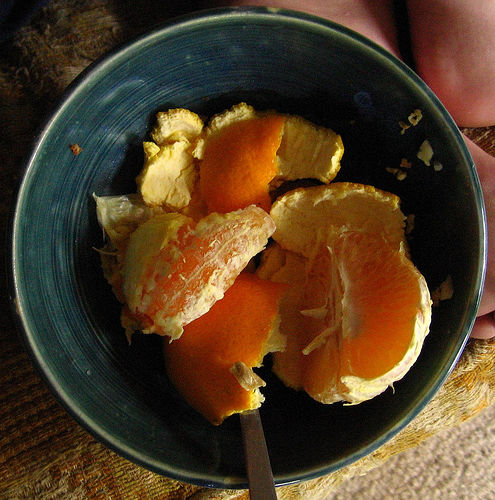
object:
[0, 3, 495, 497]
bowl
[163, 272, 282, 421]
peel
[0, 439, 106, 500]
counter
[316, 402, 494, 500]
ground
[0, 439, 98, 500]
mat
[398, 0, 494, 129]
feet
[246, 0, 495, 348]
person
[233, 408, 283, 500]
utensil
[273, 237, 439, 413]
orange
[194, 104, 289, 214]
peel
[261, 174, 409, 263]
peel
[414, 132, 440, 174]
chip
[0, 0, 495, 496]
couch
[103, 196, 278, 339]
meat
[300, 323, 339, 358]
seed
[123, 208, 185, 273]
white skin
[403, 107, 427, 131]
spots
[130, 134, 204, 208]
peels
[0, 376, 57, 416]
stripes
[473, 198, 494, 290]
light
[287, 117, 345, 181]
peal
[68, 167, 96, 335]
lines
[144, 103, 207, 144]
peal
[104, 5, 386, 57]
side